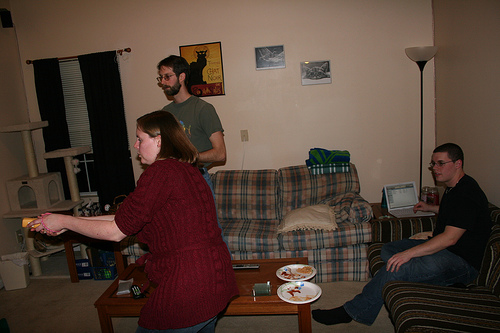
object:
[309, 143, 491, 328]
man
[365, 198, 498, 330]
couch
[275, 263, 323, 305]
plate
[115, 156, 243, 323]
sweater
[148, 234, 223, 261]
waist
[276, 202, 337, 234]
pillow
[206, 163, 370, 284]
sofa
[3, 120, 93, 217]
cat house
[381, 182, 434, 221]
laptop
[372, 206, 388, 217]
table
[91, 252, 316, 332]
table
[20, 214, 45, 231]
controller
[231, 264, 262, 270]
remote control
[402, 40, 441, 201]
lamp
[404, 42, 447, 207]
corner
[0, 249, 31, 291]
can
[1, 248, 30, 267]
plastic bag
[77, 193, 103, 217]
toys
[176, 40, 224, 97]
picture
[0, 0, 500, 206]
wall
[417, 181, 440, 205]
candles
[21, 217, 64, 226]
wii game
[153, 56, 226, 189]
man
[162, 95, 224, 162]
green shirt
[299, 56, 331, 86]
picture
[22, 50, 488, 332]
people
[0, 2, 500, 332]
livingroom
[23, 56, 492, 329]
men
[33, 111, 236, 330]
woman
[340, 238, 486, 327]
jeans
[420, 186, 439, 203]
containers